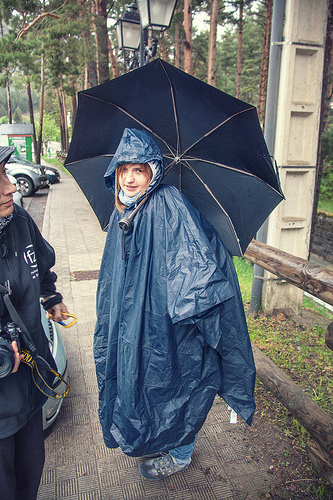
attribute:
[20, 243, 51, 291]
logo — white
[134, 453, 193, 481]
shoe — tennis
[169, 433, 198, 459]
jeans — blue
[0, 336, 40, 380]
camera — black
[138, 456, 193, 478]
tennis shoe — grey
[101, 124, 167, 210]
hood — blue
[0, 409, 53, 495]
pants — black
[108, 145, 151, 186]
face — girl's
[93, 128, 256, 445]
slicker — blue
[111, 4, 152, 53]
lamp — black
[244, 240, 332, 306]
fence — wooden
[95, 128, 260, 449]
tarp — blue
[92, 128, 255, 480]
person — rain-soaked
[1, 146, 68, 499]
person — rain-soaked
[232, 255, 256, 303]
grass — green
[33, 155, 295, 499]
sidewalk — pictured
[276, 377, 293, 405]
part — wooden, brown, long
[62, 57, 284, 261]
umbrella — large, black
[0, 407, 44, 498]
pants — black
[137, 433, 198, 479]
jeans — blue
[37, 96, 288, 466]
raincoat — girl's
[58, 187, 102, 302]
cement sidewalk — tiled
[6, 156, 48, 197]
vehicle — pictured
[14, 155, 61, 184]
vehicle — pictured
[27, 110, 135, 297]
path — grey,  stone, long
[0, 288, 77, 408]
camera — held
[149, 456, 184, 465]
shoe — pictured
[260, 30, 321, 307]
column — cement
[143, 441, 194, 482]
tennis shoes — grey, black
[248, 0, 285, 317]
post — metal